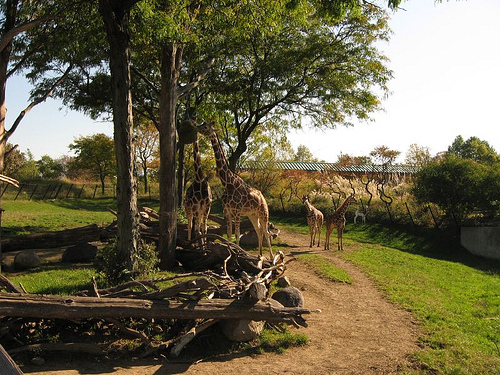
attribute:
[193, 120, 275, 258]
giraffe — eating, walking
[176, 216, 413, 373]
path — brown, dirt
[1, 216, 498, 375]
ground — grassy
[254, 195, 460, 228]
fence — leaning, black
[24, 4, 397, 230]
tree — green